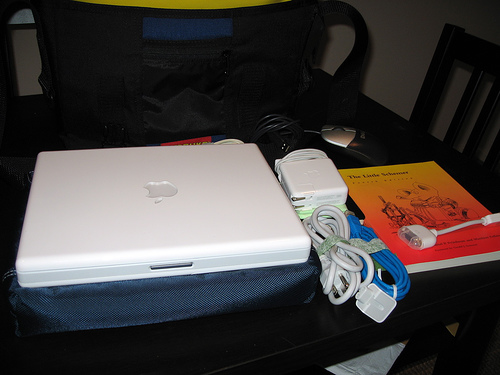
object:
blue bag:
[1, 141, 315, 333]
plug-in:
[355, 283, 393, 322]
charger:
[273, 147, 349, 208]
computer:
[15, 143, 311, 292]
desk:
[3, 45, 496, 363]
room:
[0, 10, 496, 372]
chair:
[402, 20, 498, 155]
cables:
[304, 205, 376, 303]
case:
[5, 246, 323, 331]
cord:
[348, 215, 420, 297]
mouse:
[318, 126, 388, 161]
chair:
[0, 0, 378, 102]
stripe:
[141, 17, 229, 40]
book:
[334, 159, 499, 272]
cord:
[395, 209, 499, 249]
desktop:
[24, 95, 455, 321]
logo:
[143, 180, 176, 203]